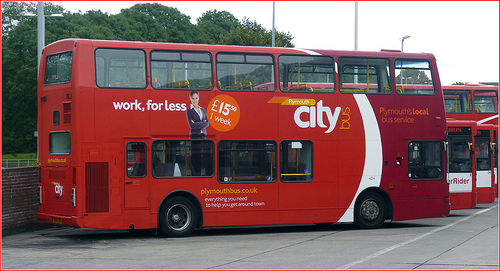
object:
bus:
[34, 38, 452, 237]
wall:
[1, 166, 47, 237]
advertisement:
[114, 89, 240, 140]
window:
[215, 51, 276, 92]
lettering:
[201, 186, 266, 209]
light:
[45, 13, 64, 18]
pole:
[36, 1, 49, 75]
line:
[337, 204, 498, 269]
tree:
[0, 0, 297, 157]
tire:
[160, 195, 200, 238]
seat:
[174, 80, 190, 89]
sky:
[0, 0, 500, 86]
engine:
[38, 164, 79, 217]